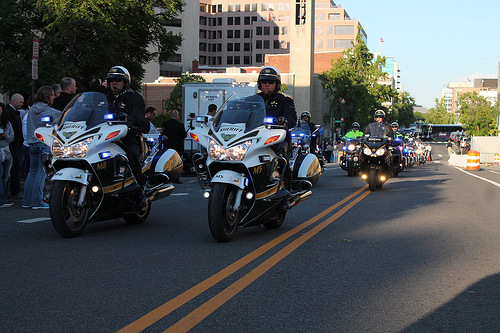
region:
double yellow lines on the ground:
[191, 251, 300, 291]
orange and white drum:
[460, 149, 482, 173]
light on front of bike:
[263, 132, 288, 151]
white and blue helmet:
[248, 62, 292, 86]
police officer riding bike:
[167, 60, 328, 247]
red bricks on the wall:
[318, 51, 340, 75]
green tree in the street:
[61, 12, 138, 48]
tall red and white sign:
[20, 30, 49, 84]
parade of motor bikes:
[205, 74, 437, 201]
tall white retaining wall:
[463, 120, 495, 167]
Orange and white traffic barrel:
[463, 149, 479, 172]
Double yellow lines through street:
[110, 179, 375, 331]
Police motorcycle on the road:
[190, 94, 325, 238]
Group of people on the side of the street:
[0, 78, 80, 210]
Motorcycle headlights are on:
[205, 134, 255, 159]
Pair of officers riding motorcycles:
[29, 64, 324, 240]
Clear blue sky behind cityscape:
[328, 0, 498, 107]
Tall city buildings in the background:
[119, 0, 499, 124]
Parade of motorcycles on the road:
[28, 66, 432, 246]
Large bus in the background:
[421, 121, 465, 144]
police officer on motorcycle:
[67, 57, 161, 212]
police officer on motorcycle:
[199, 63, 313, 230]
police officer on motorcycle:
[360, 103, 398, 187]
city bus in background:
[425, 115, 467, 145]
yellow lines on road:
[170, 258, 235, 326]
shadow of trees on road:
[325, 232, 435, 289]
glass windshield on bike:
[78, 89, 99, 114]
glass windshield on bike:
[215, 88, 261, 125]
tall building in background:
[193, 5, 382, 138]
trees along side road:
[328, 50, 367, 115]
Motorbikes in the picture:
[39, 69, 320, 233]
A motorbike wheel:
[203, 178, 256, 238]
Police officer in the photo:
[217, 43, 307, 195]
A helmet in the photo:
[247, 64, 288, 78]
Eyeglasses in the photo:
[257, 77, 283, 85]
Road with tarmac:
[286, 248, 413, 307]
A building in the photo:
[280, 19, 338, 67]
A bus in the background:
[420, 124, 469, 139]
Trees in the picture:
[330, 67, 395, 116]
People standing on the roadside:
[7, 70, 54, 190]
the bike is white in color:
[184, 84, 307, 234]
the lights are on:
[208, 135, 258, 167]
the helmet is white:
[255, 61, 285, 93]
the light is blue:
[97, 145, 116, 160]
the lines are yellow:
[182, 232, 299, 311]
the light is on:
[201, 183, 257, 209]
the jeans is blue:
[20, 141, 45, 211]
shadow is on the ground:
[423, 273, 498, 331]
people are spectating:
[6, 78, 46, 208]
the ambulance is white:
[179, 68, 254, 148]